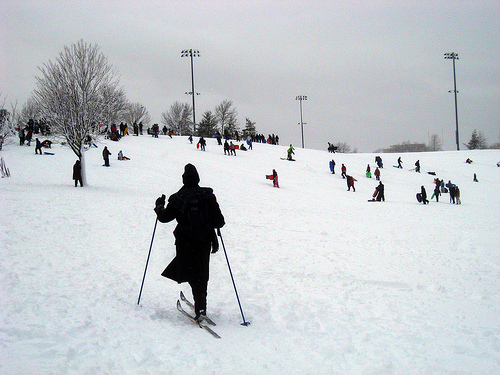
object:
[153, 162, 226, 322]
person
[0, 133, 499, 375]
hill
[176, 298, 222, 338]
skis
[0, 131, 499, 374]
snow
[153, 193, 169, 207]
hand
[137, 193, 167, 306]
ski pole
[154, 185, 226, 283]
coat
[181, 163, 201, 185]
head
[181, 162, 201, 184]
cap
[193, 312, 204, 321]
feet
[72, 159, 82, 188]
person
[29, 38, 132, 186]
tree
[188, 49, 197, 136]
lamp post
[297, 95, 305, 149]
lamp post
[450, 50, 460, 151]
lamp post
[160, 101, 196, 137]
tree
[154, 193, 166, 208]
glove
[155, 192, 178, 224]
arm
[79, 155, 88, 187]
trunk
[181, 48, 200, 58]
lights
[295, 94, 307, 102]
lights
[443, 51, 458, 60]
lights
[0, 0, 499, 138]
sky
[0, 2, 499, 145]
clouds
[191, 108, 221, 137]
tree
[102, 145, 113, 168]
people